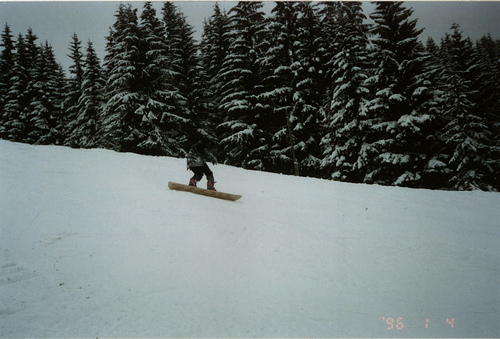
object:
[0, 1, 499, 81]
sky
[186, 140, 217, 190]
person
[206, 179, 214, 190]
snow boot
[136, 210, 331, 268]
ski mark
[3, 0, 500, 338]
snow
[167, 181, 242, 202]
skyboard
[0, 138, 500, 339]
hill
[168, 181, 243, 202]
snowboard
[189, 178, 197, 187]
boot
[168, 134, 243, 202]
skier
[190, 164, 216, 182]
black pants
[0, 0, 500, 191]
pine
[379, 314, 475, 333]
numbers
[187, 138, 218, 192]
snow boarder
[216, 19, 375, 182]
fir trees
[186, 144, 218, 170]
coat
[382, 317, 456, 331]
date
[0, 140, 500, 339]
ski slope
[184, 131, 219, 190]
boarder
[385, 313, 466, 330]
photograph